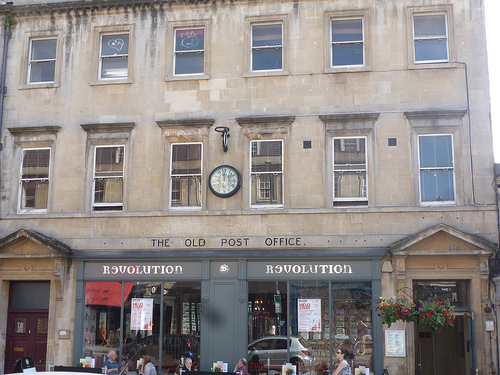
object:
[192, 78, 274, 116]
wall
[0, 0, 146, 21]
roof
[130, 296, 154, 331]
graphic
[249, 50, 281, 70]
glass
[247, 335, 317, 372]
car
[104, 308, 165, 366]
door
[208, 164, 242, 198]
clock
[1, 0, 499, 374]
building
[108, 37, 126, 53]
heart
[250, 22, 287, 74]
window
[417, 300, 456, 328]
flowers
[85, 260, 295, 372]
entries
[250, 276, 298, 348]
reflection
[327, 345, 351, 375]
woman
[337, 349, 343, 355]
sunglasses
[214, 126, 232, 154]
pipe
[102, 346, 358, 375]
people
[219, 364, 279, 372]
tables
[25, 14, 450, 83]
windows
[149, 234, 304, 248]
lettering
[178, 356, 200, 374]
man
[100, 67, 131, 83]
sign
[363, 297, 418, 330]
plants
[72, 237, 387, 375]
store front